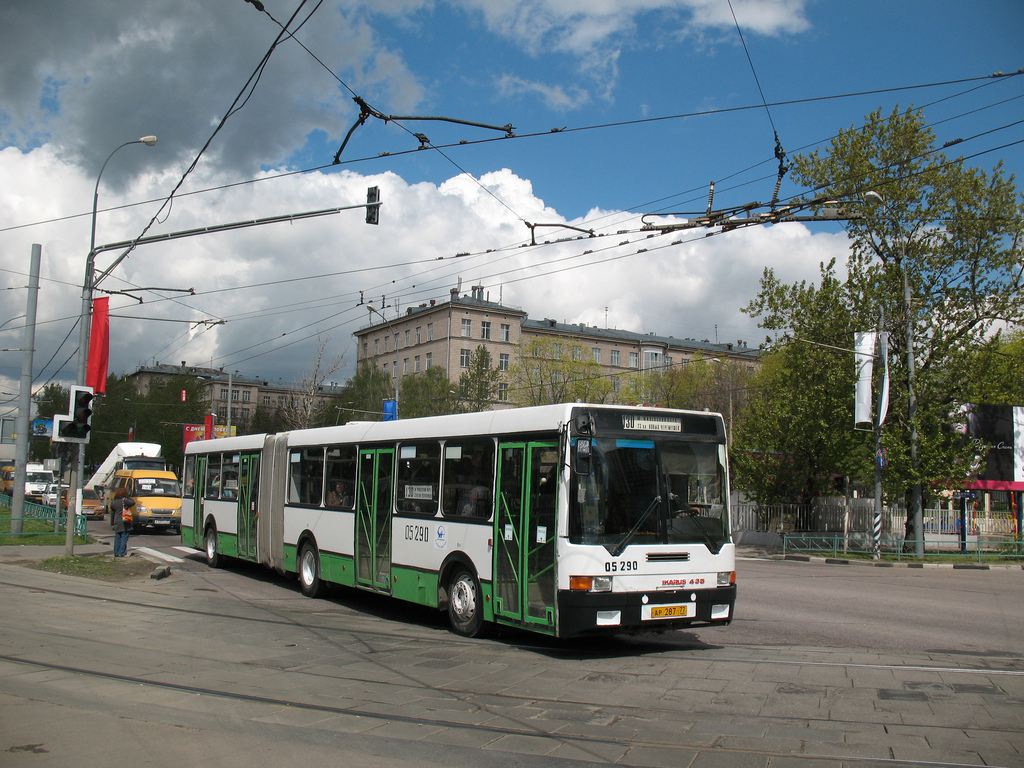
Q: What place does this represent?
A: It represents the pavement.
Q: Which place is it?
A: It is a pavement.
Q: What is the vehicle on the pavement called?
A: The vehicle is a car.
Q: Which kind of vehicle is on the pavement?
A: The vehicle is a car.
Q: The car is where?
A: The car is on the pavement.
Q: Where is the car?
A: The car is on the pavement.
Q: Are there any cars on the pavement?
A: Yes, there is a car on the pavement.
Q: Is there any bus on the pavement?
A: No, there is a car on the pavement.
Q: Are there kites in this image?
A: No, there are no kites.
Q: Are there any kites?
A: No, there are no kites.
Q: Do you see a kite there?
A: No, there are no kites.